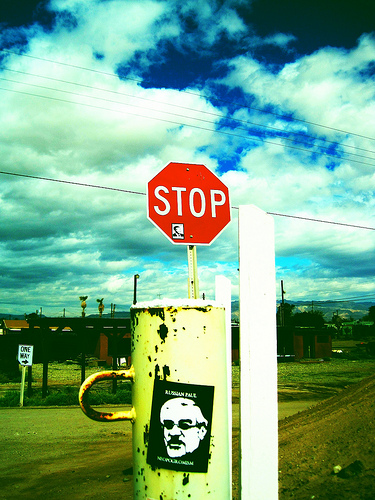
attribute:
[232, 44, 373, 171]
cloud — puffy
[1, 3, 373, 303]
sky — blue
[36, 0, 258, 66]
cloud — puffy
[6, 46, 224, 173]
cloud — puffy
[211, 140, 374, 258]
cloud — puffy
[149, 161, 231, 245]
sign — stop, red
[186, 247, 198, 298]
pole — metal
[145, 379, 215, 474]
poster — black, white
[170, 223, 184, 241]
sticker — black, white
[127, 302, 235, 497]
post — yellow, black, rusty, cement